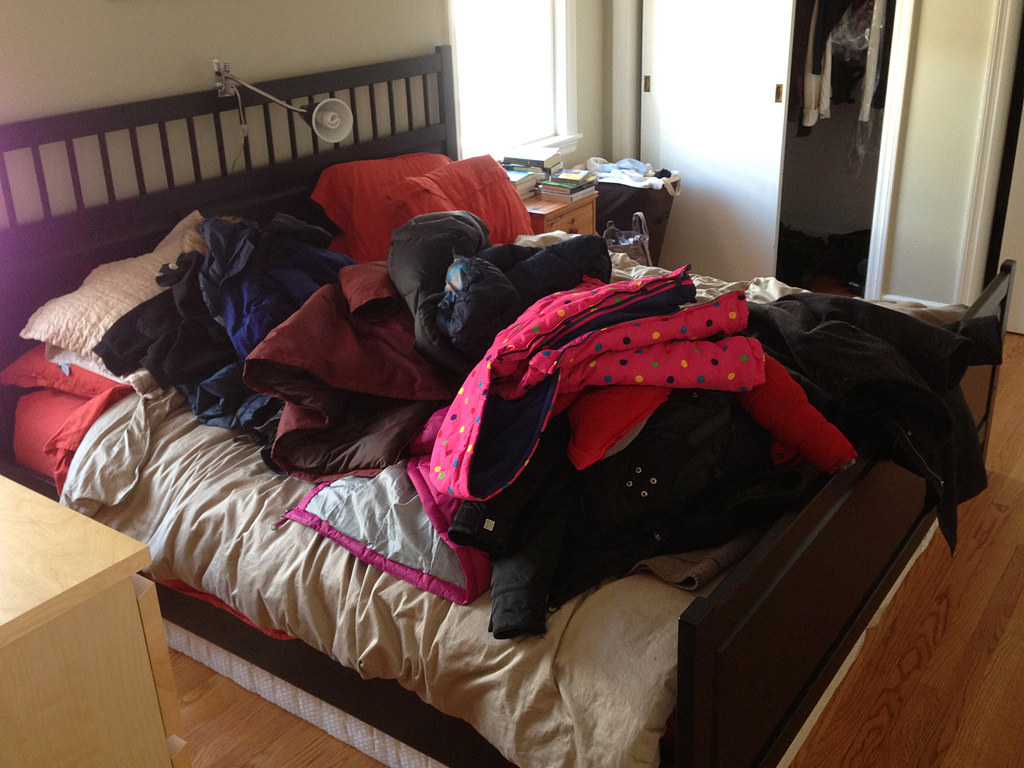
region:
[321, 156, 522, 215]
orange pillows on the bed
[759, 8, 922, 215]
Clothes hanging in closet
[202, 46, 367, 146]
a light clipped on to a bed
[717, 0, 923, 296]
a bedroom closet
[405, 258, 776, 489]
a pink polka dotted coat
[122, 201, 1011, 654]
a pile of coats on a bed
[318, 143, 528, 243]
red pillows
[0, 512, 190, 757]
the corner of a dresser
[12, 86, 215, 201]
a brown headboard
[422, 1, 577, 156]
a bedroom window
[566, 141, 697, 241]
laundry hamper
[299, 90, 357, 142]
a light bulb in a lamp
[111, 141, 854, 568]
a jumble of clothing on a bed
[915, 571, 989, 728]
the floor is covered in wood panels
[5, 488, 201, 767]
a set of drawers in light wood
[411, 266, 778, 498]
pink polka dot jacket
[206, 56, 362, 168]
a light attached to a headboard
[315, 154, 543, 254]
two red-covered pillows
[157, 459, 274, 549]
a tan colored bedspread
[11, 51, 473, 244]
a dark headboard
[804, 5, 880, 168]
clothes hanging in a closet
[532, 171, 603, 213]
books stacked on a set of drawers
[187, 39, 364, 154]
clip on reading lamp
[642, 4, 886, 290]
open closet door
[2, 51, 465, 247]
wooden bed headboard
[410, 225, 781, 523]
pink coat with colored polka dots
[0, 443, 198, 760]
light wood dresser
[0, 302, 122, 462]
red bed sheets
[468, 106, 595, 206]
books stacked on night stand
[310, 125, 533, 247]
pillows in red cases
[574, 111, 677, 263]
laundry hamper full of clothes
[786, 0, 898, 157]
clothing hanging in closet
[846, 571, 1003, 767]
Hardwood flooring under bed.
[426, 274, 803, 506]
A pink coat of a child.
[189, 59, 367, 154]
A lamp hanging onto headboard.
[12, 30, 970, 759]
A full sized bed with coats.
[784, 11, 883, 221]
Clothing in the closet.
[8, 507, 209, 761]
A wooden piece of furniture.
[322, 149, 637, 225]
Two red pillow on bed.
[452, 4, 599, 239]
A pile of books.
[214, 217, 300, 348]
A blue coat on bed.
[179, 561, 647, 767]
A comforter on bed.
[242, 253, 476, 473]
A maroon jacket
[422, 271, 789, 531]
Pink jacket with colorful polka dots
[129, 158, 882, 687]
Many jackets on a bed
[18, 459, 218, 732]
A light brown dresser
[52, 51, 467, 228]
A dark brown headboard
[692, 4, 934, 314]
A closet door is open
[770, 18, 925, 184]
Clothes are hanging in a closet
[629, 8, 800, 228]
A white closet door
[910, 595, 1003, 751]
A brown wooden floor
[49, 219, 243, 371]
A white pillow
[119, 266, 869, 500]
various coats are piled up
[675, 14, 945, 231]
closet door is open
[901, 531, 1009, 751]
floor is wood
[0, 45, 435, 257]
reading lamp attached to headboard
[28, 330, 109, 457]
bed has red sheets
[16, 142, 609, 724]
furniture does not match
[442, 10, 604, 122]
light comes in from window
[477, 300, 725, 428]
pink coat with polka dots